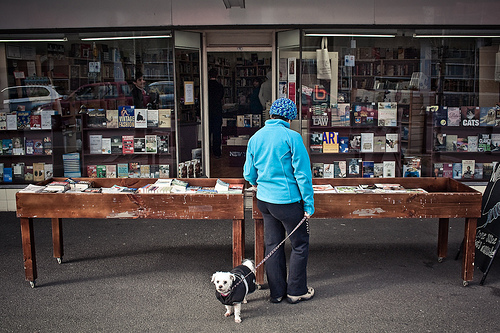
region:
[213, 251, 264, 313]
small dogin outfit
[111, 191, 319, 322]
person holding a dog leash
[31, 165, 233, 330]
wooden tablwe with books on top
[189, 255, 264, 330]
small white dog on leash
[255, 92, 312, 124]
person wearing a blue hat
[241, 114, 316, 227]
person wearing a blue jacket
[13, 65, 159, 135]
reflection in a window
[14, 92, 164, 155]
books in a store front window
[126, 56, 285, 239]
doorway to a book store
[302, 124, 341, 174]
yellow book with blue writing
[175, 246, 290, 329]
This is a small dog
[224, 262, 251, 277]
This is a lease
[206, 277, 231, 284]
These are eyes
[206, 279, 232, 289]
The eyes are black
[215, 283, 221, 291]
This is a nose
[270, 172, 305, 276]
The pants are black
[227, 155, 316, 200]
The sweatshirt is blue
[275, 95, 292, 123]
This is a hat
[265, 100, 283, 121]
The hat is blue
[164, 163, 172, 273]
This is a wooden stand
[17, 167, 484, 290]
Wooden stands with books on them.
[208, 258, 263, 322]
A white dog.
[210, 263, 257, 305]
A black dog coat.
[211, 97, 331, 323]
A woman walking her dog.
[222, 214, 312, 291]
A dog leash.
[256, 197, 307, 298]
A pair of black pants.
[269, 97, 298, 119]
A knit blue tobogan.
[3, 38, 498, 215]
A bookstore.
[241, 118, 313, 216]
A light blue fleece jacket.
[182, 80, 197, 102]
A white sign on the door.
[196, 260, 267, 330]
the dog is white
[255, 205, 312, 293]
the jeans are dark blue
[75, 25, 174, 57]
the light is on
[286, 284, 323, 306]
the shoe is white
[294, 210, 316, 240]
the woman is holding the leash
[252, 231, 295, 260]
the leash is multi-colored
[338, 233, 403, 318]
the ground is gray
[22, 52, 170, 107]
the reflection is in the window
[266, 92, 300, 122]
the hat is blue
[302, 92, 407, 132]
the books are on a shelf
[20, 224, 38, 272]
the leg is brown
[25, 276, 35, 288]
the the leg is on a wheel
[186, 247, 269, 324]
the dog is wearing a vest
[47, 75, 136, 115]
the SUV is red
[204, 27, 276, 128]
the door is open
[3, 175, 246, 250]
the table is wooden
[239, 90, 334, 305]
the woman is looking at books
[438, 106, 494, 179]
the books are on shelves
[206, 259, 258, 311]
the vest is black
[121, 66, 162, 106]
the woman is inside the bookstore